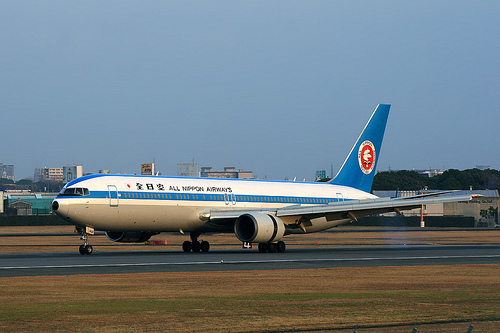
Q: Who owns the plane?
A: All Nippon Airways.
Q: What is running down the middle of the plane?
A: Blue stripe.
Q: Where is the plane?
A: On the runway.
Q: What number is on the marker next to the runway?
A: 4.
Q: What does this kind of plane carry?
A: Passengers.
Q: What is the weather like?
A: Clear and sunny.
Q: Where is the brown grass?
A: Next to the runway.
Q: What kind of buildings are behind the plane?
A: High rise buildings.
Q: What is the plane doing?
A: Taxiing on the runway.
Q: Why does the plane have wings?
A: To fly.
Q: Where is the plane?
A: On the tarmac.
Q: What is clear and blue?
A: Sky.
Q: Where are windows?
A: On the plane.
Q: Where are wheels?
A: Under the plane.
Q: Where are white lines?
A: On the tarmac.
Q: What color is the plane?
A: White, blue.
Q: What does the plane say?
A: All nippon airways.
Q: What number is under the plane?
A: 4.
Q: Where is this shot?
A: Tarmac.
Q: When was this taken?
A: Daytime.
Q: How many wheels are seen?
A: 8.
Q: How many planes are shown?
A: 1.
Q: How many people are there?
A: 0.